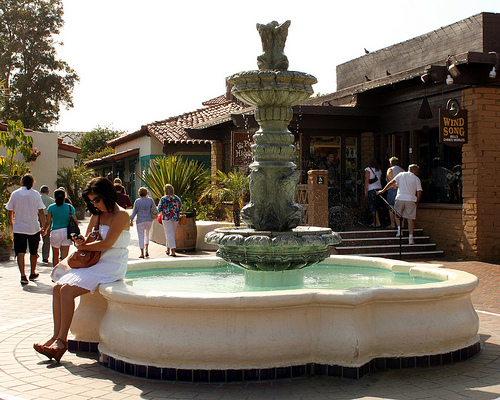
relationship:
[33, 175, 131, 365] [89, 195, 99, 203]
woman wearing sunglasses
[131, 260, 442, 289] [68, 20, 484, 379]
water inside fountain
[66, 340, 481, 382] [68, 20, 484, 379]
brick around fountain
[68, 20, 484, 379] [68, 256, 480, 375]
fountain in center of basin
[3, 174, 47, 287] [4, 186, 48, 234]
man wearing shirt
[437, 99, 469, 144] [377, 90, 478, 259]
sign hanging on wall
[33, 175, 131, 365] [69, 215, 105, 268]
woman holding purse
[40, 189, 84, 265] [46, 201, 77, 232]
woman wearing shirt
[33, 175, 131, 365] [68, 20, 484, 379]
woman sitting on fountain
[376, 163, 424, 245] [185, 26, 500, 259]
man going into building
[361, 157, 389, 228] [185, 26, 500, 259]
woman going into building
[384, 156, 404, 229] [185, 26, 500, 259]
woman going into building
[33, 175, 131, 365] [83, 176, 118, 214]
woman has hair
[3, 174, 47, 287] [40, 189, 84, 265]
man walking with woman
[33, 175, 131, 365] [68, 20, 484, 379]
woman sitting by fountain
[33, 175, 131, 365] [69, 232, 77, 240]
woman checking cellphone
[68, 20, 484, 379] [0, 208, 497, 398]
fountain located in plaza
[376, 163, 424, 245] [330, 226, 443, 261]
man walking up stairs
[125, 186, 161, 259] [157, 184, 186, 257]
woman walking with woman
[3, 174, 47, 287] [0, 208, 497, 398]
man walking in plaza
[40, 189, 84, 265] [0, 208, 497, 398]
woman walking in plaza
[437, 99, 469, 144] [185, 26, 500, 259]
sign hanging from building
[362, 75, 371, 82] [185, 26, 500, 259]
bird sitting on building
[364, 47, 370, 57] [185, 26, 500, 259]
bird sitting on building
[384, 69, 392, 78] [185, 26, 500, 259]
bird sitting on building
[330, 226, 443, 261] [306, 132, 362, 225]
stairs lead to entrance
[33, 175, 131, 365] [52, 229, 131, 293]
woman wearing dress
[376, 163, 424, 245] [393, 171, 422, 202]
man wearing shirt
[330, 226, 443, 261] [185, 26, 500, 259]
stairs in front of building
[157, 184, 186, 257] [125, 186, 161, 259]
woman walking with woman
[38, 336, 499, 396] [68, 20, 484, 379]
shadow cast by fountain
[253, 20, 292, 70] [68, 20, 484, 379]
statue in middle of fountain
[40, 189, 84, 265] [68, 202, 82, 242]
woman carrying purse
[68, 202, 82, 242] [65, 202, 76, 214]
purse hanging from shoulder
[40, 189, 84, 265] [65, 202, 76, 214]
woman has shoulder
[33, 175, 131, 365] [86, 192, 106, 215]
woman has face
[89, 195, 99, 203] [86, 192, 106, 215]
sunglasses worn on face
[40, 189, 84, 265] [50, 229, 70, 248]
woman wearing shorts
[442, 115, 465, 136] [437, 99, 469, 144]
letters painted on sign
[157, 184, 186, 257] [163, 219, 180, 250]
woman wearing pants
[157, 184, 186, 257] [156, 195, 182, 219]
woman wearing shirt